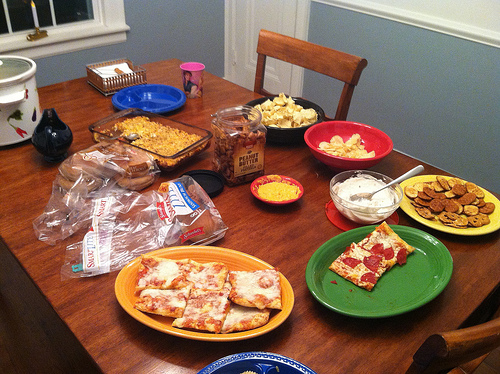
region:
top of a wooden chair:
[256, 28, 371, 92]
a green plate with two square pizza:
[309, 229, 450, 305]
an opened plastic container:
[213, 100, 263, 170]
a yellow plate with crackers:
[415, 168, 499, 235]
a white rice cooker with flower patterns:
[1, 47, 35, 144]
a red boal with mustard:
[250, 172, 308, 207]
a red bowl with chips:
[316, 119, 394, 163]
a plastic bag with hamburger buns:
[51, 137, 147, 187]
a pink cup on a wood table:
[183, 60, 208, 101]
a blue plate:
[123, 82, 185, 109]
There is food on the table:
[78, 86, 485, 369]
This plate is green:
[314, 234, 464, 331]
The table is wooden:
[13, 149, 148, 317]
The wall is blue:
[395, 27, 479, 151]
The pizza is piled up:
[124, 256, 296, 348]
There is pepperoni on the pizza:
[315, 243, 396, 296]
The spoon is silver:
[344, 165, 435, 217]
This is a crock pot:
[0, 35, 86, 185]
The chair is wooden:
[234, 18, 384, 125]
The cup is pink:
[171, 51, 214, 100]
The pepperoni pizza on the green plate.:
[326, 226, 414, 284]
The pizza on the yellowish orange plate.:
[138, 248, 288, 335]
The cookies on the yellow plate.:
[406, 177, 491, 228]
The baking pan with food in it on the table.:
[91, 110, 218, 168]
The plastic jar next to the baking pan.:
[211, 96, 268, 187]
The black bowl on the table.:
[236, 95, 319, 134]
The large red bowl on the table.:
[303, 110, 396, 165]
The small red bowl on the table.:
[247, 175, 300, 211]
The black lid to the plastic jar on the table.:
[178, 161, 225, 191]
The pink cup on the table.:
[178, 55, 214, 100]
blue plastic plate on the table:
[113, 76, 183, 118]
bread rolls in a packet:
[140, 176, 230, 241]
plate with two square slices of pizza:
[315, 218, 458, 338]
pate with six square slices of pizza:
[121, 229, 289, 336]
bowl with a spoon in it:
[328, 161, 407, 216]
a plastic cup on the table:
[175, 62, 217, 103]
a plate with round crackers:
[403, 168, 493, 234]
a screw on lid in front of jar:
[176, 163, 234, 200]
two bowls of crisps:
[240, 86, 399, 174]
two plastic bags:
[49, 130, 213, 248]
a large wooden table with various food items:
[13, 53, 495, 369]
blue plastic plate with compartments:
[110, 77, 186, 117]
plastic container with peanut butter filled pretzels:
[205, 95, 265, 177]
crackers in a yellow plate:
[395, 167, 496, 234]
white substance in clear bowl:
[327, 158, 427, 218]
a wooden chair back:
[246, 23, 369, 124]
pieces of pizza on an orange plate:
[117, 235, 292, 340]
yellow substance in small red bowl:
[242, 167, 308, 213]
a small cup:
[174, 55, 212, 102]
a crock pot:
[0, 47, 43, 158]